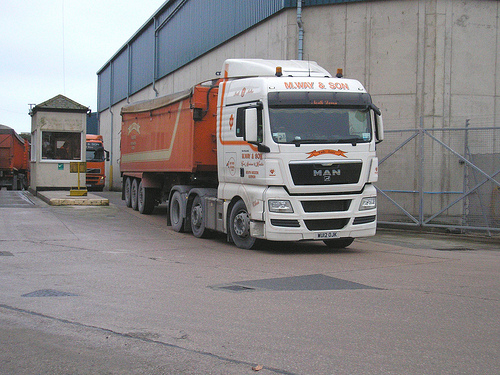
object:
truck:
[116, 58, 385, 249]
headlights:
[267, 196, 377, 214]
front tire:
[229, 199, 257, 250]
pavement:
[0, 192, 500, 374]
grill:
[249, 185, 379, 242]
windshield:
[268, 104, 373, 144]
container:
[120, 84, 223, 173]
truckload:
[115, 78, 222, 180]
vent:
[218, 285, 255, 293]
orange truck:
[86, 132, 111, 192]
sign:
[69, 162, 87, 174]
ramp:
[0, 185, 33, 207]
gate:
[382, 128, 500, 236]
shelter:
[27, 94, 92, 191]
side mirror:
[243, 107, 259, 142]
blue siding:
[95, 0, 284, 114]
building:
[94, 0, 498, 235]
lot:
[0, 119, 499, 302]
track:
[1, 190, 36, 209]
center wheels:
[169, 191, 217, 238]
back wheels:
[124, 177, 155, 215]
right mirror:
[371, 103, 383, 144]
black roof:
[30, 94, 90, 112]